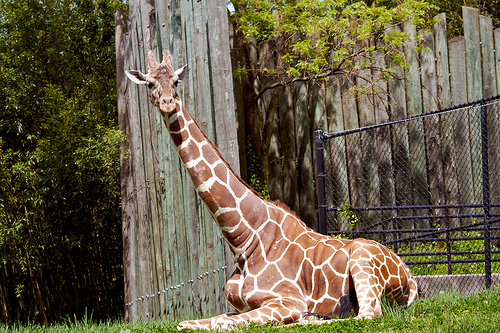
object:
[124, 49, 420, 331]
giraffe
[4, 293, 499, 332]
ground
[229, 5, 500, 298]
fence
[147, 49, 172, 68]
horns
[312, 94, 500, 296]
gate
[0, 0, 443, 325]
trees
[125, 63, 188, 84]
ears